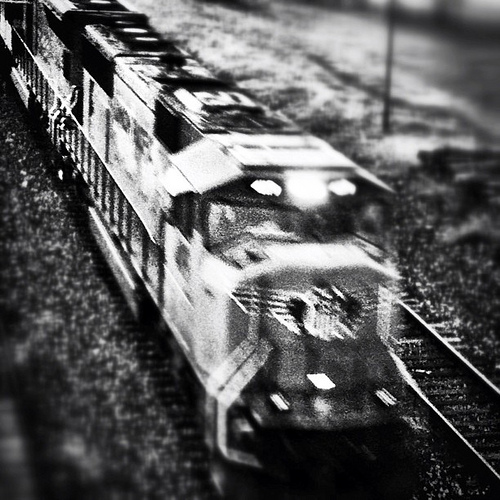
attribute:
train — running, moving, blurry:
[6, 2, 399, 494]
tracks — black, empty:
[399, 307, 498, 488]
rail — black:
[46, 154, 121, 288]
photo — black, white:
[3, 2, 497, 423]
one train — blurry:
[119, 61, 414, 463]